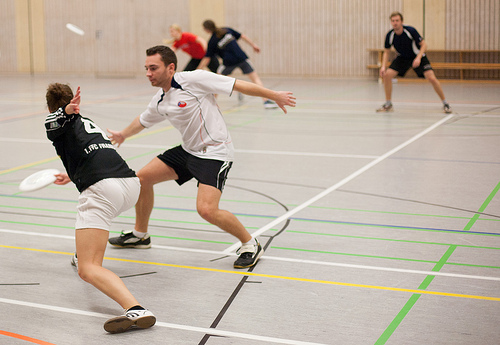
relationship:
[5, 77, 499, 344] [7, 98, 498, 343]
grey floor with painted lines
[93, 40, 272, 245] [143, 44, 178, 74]
man with hair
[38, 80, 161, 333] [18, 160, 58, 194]
girl holding frisbee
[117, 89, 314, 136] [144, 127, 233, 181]
arms extended out sides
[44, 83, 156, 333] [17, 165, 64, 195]
girl bent over with a frisbee